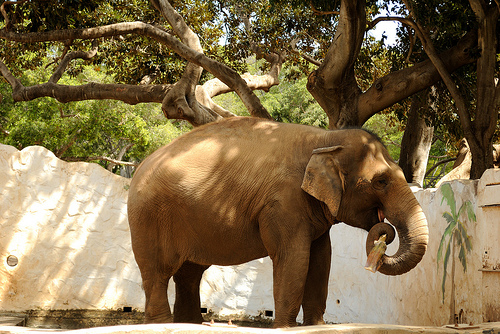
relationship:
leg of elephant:
[268, 232, 315, 328] [126, 115, 429, 327]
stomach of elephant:
[164, 137, 274, 255] [126, 115, 429, 327]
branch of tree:
[1, 48, 195, 121] [34, 28, 174, 148]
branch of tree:
[285, 19, 430, 115] [297, 2, 495, 182]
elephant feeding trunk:
[126, 115, 429, 327] [360, 183, 430, 278]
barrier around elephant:
[1, 141, 497, 328] [126, 115, 429, 327]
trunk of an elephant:
[361, 176, 430, 285] [126, 115, 429, 327]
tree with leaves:
[0, 3, 500, 180] [45, 96, 112, 146]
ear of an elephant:
[266, 134, 352, 221] [92, 121, 426, 330]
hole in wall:
[260, 304, 280, 322] [5, 179, 108, 306]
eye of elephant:
[371, 171, 383, 191] [86, 119, 451, 328]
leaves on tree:
[235, 2, 329, 63] [0, 3, 500, 180]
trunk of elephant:
[363, 180, 429, 278] [126, 115, 429, 327]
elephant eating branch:
[126, 115, 429, 327] [358, 227, 393, 272]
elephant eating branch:
[126, 115, 429, 327] [364, 232, 387, 272]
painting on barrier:
[437, 188, 481, 300] [1, 141, 497, 328]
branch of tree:
[122, 12, 326, 147] [0, 2, 498, 185]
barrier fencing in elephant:
[1, 141, 497, 328] [126, 115, 429, 327]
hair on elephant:
[289, 119, 378, 144] [126, 115, 429, 327]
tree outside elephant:
[0, 3, 500, 180] [126, 115, 429, 327]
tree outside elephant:
[396, 0, 466, 187] [126, 115, 429, 327]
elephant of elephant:
[126, 115, 429, 327] [126, 115, 429, 327]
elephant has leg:
[104, 124, 439, 324] [248, 203, 311, 319]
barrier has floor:
[1, 141, 497, 328] [2, 314, 497, 332]